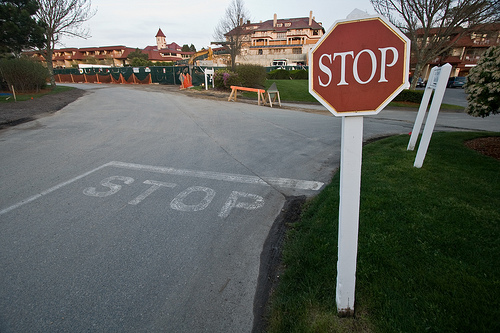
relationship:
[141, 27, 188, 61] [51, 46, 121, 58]
building for apartments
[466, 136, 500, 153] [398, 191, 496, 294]
mulch beside lawn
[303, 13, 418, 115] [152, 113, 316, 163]
sign on street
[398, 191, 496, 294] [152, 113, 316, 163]
lawn beside street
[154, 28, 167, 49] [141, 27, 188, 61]
tower on top of building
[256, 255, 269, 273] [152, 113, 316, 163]
water on top of street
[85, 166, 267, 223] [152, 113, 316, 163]
stop on top of street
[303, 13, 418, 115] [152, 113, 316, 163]
sign beside street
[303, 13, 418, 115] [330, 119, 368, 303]
sign made of wood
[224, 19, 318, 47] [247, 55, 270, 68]
building made of stone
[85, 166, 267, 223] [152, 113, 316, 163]
stop written on street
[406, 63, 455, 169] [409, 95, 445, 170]
sign has posts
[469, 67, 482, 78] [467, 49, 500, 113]
flowers are on side of tree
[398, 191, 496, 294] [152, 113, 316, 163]
lawn near street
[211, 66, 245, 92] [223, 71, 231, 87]
shrub has flowers